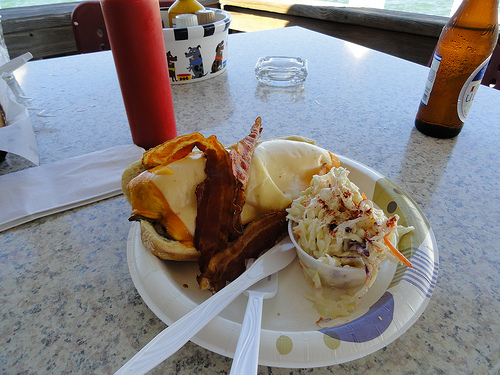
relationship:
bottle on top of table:
[416, 1, 500, 139] [4, 26, 494, 372]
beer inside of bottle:
[417, 23, 499, 139] [416, 1, 500, 139]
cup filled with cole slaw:
[289, 216, 397, 285] [293, 169, 405, 269]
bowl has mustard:
[160, 8, 230, 86] [167, 0, 207, 31]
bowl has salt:
[160, 8, 230, 86] [169, 15, 200, 27]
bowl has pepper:
[160, 8, 230, 86] [191, 9, 215, 26]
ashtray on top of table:
[255, 55, 308, 88] [4, 26, 494, 372]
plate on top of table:
[124, 150, 439, 367] [4, 26, 494, 372]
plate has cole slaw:
[124, 150, 439, 367] [293, 169, 405, 269]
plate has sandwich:
[124, 150, 439, 367] [122, 153, 242, 262]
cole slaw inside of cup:
[293, 169, 405, 269] [289, 216, 397, 285]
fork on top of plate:
[226, 256, 279, 375] [124, 150, 439, 367]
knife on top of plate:
[113, 235, 298, 374] [124, 150, 439, 367]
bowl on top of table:
[160, 8, 230, 86] [4, 26, 494, 372]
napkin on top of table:
[1, 147, 146, 232] [4, 26, 494, 372]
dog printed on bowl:
[185, 44, 208, 79] [160, 8, 230, 86]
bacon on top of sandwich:
[138, 133, 237, 254] [122, 153, 242, 262]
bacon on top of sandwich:
[139, 117, 294, 298] [122, 153, 242, 262]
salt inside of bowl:
[169, 15, 200, 27] [160, 8, 230, 86]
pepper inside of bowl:
[191, 9, 215, 26] [160, 8, 230, 86]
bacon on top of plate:
[138, 133, 237, 254] [124, 150, 439, 367]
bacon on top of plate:
[139, 117, 294, 298] [124, 150, 439, 367]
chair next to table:
[72, 0, 174, 53] [4, 26, 494, 372]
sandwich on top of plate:
[122, 153, 242, 262] [124, 150, 439, 367]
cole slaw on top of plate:
[293, 169, 405, 269] [124, 150, 439, 367]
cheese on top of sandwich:
[152, 141, 336, 234] [122, 153, 242, 262]